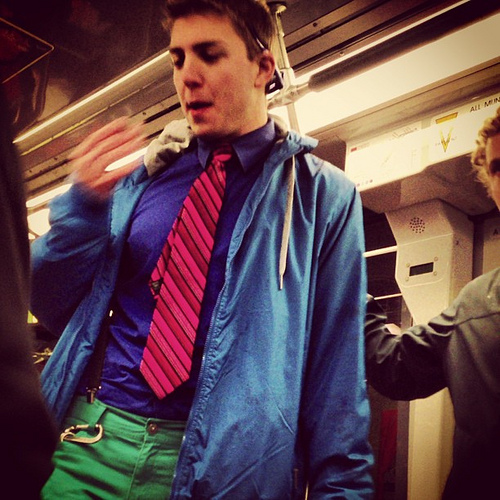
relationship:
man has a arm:
[364, 102, 498, 499] [364, 294, 454, 403]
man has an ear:
[38, 0, 378, 497] [255, 50, 276, 88]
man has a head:
[38, 0, 378, 497] [167, 4, 280, 142]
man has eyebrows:
[38, 0, 378, 497] [165, 39, 228, 55]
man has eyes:
[38, 0, 378, 497] [168, 46, 228, 65]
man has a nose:
[38, 0, 378, 497] [182, 54, 205, 88]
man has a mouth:
[38, 0, 378, 497] [184, 100, 217, 113]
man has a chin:
[38, 0, 378, 497] [191, 119, 225, 135]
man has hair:
[38, 0, 378, 497] [160, 0, 275, 61]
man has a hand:
[38, 0, 378, 497] [68, 114, 149, 193]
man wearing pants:
[38, 0, 378, 497] [37, 390, 188, 500]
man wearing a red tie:
[38, 0, 378, 497] [138, 148, 232, 400]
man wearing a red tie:
[38, 0, 378, 497] [138, 138, 236, 404]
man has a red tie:
[38, 0, 378, 497] [138, 148, 232, 400]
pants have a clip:
[37, 390, 188, 500] [60, 423, 105, 445]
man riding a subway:
[38, 0, 378, 497] [2, 1, 500, 499]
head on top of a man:
[167, 4, 280, 142] [38, 0, 378, 497]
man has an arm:
[38, 0, 378, 497] [27, 139, 163, 337]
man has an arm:
[364, 109, 497, 498] [364, 295, 457, 409]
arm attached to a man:
[364, 295, 457, 409] [364, 109, 497, 498]